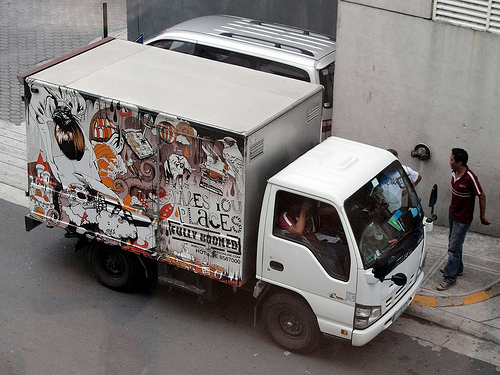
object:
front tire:
[259, 289, 321, 352]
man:
[279, 195, 352, 270]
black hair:
[451, 148, 468, 168]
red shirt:
[449, 165, 484, 224]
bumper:
[350, 235, 429, 348]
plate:
[373, 230, 385, 240]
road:
[0, 194, 480, 345]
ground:
[0, 197, 500, 373]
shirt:
[279, 207, 322, 248]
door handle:
[269, 260, 284, 271]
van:
[139, 14, 337, 144]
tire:
[88, 240, 150, 290]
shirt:
[379, 164, 420, 213]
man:
[435, 148, 494, 291]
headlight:
[354, 303, 381, 330]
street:
[38, 250, 254, 341]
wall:
[331, 0, 500, 240]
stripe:
[467, 170, 482, 194]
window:
[343, 160, 425, 270]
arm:
[476, 185, 486, 218]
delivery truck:
[17, 36, 429, 351]